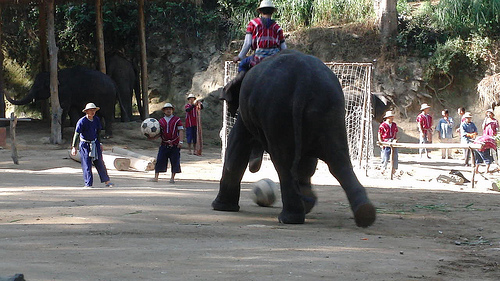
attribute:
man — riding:
[236, 0, 288, 58]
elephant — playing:
[212, 53, 375, 227]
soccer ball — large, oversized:
[139, 116, 161, 140]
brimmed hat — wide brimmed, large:
[82, 101, 101, 114]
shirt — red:
[246, 16, 284, 50]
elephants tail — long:
[289, 87, 307, 201]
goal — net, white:
[344, 60, 377, 179]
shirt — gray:
[237, 34, 250, 61]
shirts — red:
[160, 117, 185, 146]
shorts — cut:
[153, 140, 181, 172]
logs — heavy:
[105, 141, 156, 179]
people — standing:
[378, 101, 499, 168]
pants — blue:
[80, 139, 109, 186]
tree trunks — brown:
[137, 1, 150, 116]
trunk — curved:
[3, 66, 46, 124]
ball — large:
[251, 176, 279, 212]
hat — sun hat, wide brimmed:
[257, 0, 280, 12]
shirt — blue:
[74, 117, 102, 139]